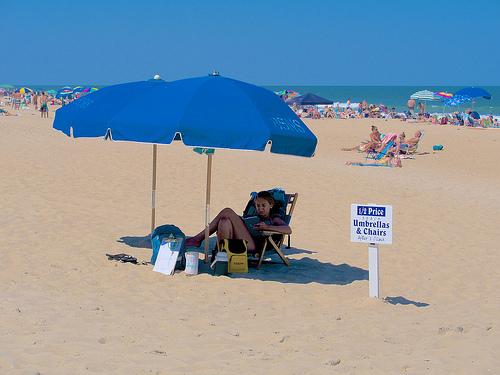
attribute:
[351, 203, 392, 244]
sign — blue, white, half price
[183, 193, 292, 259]
woman — sitting, laying, reading, young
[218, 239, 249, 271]
bag — black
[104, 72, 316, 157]
umbrella — blue, half priced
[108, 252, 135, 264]
sandals — black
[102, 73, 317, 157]
canopy — blue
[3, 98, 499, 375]
sand — brown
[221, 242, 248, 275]
item — yellow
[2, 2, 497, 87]
sky — blue